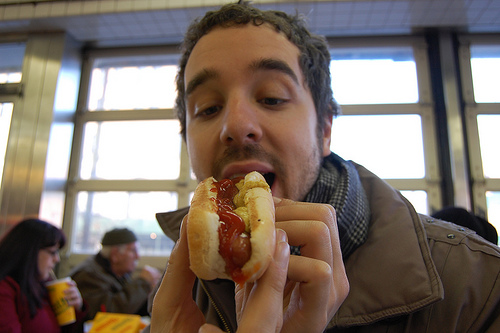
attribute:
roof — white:
[86, 8, 176, 24]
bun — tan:
[178, 194, 219, 273]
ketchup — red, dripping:
[224, 214, 245, 239]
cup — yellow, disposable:
[49, 277, 81, 331]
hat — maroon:
[105, 227, 134, 244]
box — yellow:
[92, 303, 147, 329]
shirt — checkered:
[324, 194, 353, 230]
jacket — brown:
[401, 219, 456, 311]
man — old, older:
[99, 222, 147, 293]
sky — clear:
[90, 76, 170, 122]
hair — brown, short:
[307, 21, 336, 102]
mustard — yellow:
[233, 187, 249, 228]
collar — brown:
[98, 243, 118, 268]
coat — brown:
[90, 263, 137, 304]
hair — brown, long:
[4, 206, 43, 311]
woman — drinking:
[7, 203, 75, 326]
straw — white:
[49, 267, 59, 278]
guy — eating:
[139, 47, 346, 274]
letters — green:
[49, 297, 75, 313]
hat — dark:
[439, 194, 499, 232]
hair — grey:
[96, 247, 123, 262]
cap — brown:
[112, 224, 144, 249]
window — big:
[349, 51, 428, 184]